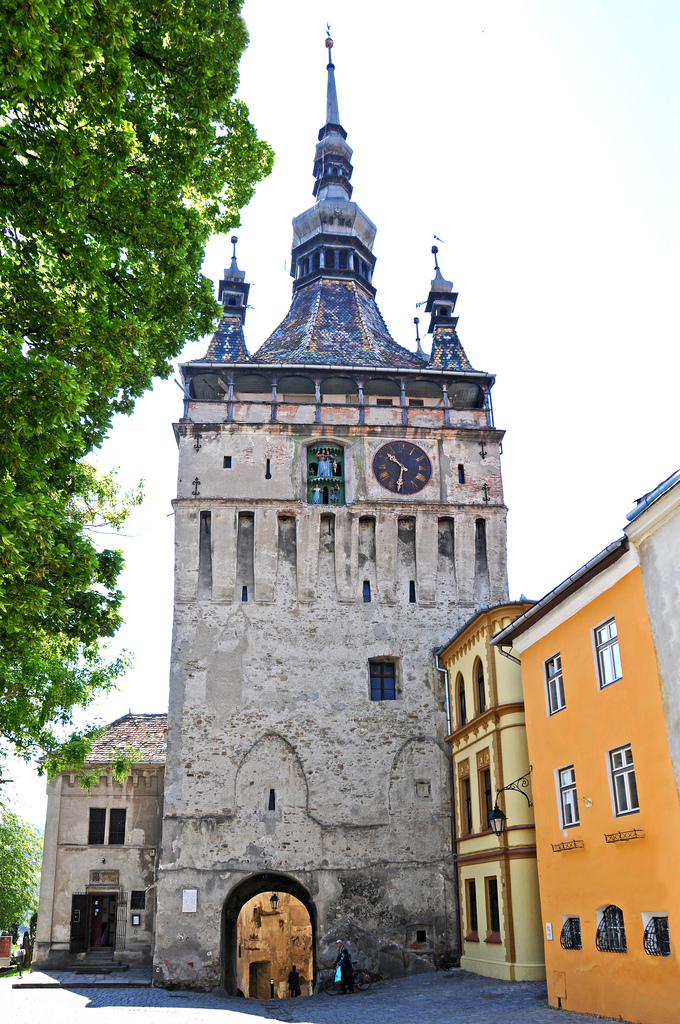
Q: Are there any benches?
A: No, there are no benches.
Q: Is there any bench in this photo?
A: No, there are no benches.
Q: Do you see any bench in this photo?
A: No, there are no benches.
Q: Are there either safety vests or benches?
A: No, there are no benches or safety vests.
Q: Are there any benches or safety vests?
A: No, there are no benches or safety vests.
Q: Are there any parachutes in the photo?
A: No, there are no parachutes.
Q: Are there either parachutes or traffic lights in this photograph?
A: No, there are no parachutes or traffic lights.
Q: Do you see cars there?
A: No, there are no cars.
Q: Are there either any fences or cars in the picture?
A: No, there are no cars or fences.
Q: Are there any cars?
A: No, there are no cars.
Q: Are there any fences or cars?
A: No, there are no cars or fences.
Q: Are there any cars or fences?
A: No, there are no cars or fences.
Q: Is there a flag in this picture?
A: No, there are no flags.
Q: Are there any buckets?
A: No, there are no buckets.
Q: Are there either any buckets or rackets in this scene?
A: No, there are no buckets or rackets.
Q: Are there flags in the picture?
A: No, there are no flags.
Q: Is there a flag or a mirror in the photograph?
A: No, there are no flags or mirrors.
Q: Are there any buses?
A: No, there are no buses.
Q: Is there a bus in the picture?
A: No, there are no buses.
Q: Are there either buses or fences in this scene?
A: No, there are no buses or fences.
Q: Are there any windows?
A: Yes, there are windows.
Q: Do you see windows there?
A: Yes, there are windows.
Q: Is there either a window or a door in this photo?
A: Yes, there are windows.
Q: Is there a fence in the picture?
A: No, there are no fences.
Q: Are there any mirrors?
A: No, there are no mirrors.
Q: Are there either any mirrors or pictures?
A: No, there are no mirrors or pictures.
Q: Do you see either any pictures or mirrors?
A: No, there are no mirrors or pictures.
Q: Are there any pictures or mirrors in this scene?
A: No, there are no mirrors or pictures.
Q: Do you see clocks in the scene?
A: Yes, there is a clock.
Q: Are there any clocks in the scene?
A: Yes, there is a clock.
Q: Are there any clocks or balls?
A: Yes, there is a clock.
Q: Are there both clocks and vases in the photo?
A: No, there is a clock but no vases.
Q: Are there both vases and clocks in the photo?
A: No, there is a clock but no vases.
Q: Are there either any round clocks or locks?
A: Yes, there is a round clock.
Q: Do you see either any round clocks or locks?
A: Yes, there is a round clock.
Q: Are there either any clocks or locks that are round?
A: Yes, the clock is round.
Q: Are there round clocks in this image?
A: Yes, there is a round clock.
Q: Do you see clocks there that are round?
A: Yes, there is a clock that is round.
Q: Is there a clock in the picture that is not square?
A: Yes, there is a round clock.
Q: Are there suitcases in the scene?
A: No, there are no suitcases.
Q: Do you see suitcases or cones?
A: No, there are no suitcases or cones.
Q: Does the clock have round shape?
A: Yes, the clock is round.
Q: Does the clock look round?
A: Yes, the clock is round.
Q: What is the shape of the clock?
A: The clock is round.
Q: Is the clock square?
A: No, the clock is round.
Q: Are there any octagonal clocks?
A: No, there is a clock but it is round.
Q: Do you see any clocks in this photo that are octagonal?
A: No, there is a clock but it is round.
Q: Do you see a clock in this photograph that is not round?
A: No, there is a clock but it is round.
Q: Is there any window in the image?
A: Yes, there are windows.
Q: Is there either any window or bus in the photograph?
A: Yes, there are windows.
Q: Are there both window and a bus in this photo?
A: No, there are windows but no buses.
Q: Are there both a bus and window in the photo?
A: No, there are windows but no buses.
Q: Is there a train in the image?
A: No, there are no trains.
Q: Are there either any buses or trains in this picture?
A: No, there are no trains or buses.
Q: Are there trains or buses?
A: No, there are no trains or buses.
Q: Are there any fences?
A: No, there are no fences.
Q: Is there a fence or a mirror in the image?
A: No, there are no fences or mirrors.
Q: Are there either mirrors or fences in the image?
A: No, there are no fences or mirrors.